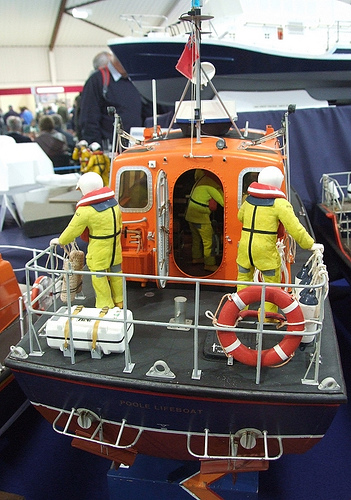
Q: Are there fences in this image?
A: No, there are no fences.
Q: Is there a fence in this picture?
A: No, there are no fences.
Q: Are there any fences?
A: No, there are no fences.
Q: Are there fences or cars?
A: No, there are no fences or cars.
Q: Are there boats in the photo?
A: Yes, there is a boat.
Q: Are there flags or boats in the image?
A: Yes, there is a boat.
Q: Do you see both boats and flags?
A: Yes, there are both a boat and a flag.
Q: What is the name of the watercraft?
A: The watercraft is a boat.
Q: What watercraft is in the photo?
A: The watercraft is a boat.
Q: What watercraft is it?
A: The watercraft is a boat.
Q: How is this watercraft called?
A: That is a boat.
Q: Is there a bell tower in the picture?
A: No, there are no bell towers.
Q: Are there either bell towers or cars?
A: No, there are no bell towers or cars.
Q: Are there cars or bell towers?
A: No, there are no bell towers or cars.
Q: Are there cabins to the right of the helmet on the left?
A: Yes, there is a cabin to the right of the helmet.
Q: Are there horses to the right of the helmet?
A: No, there is a cabin to the right of the helmet.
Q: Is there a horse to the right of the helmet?
A: No, there is a cabin to the right of the helmet.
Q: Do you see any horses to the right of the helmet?
A: No, there is a cabin to the right of the helmet.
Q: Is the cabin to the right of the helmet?
A: Yes, the cabin is to the right of the helmet.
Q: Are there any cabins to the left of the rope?
A: Yes, there is a cabin to the left of the rope.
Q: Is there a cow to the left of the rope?
A: No, there is a cabin to the left of the rope.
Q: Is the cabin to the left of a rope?
A: Yes, the cabin is to the left of a rope.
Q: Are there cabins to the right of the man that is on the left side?
A: Yes, there is a cabin to the right of the man.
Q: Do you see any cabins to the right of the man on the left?
A: Yes, there is a cabin to the right of the man.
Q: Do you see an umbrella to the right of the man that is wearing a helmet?
A: No, there is a cabin to the right of the man.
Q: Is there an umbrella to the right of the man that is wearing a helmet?
A: No, there is a cabin to the right of the man.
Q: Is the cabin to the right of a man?
A: Yes, the cabin is to the right of a man.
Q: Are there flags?
A: Yes, there is a flag.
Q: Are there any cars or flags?
A: Yes, there is a flag.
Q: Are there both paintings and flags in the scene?
A: No, there is a flag but no paintings.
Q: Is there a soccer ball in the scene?
A: No, there are no soccer balls.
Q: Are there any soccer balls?
A: No, there are no soccer balls.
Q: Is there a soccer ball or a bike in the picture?
A: No, there are no soccer balls or bikes.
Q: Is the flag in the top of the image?
A: Yes, the flag is in the top of the image.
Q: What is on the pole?
A: The flag is on the pole.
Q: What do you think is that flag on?
A: The flag is on the pole.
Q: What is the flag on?
A: The flag is on the pole.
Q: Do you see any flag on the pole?
A: Yes, there is a flag on the pole.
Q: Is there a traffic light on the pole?
A: No, there is a flag on the pole.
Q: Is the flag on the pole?
A: Yes, the flag is on the pole.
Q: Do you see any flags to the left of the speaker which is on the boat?
A: Yes, there is a flag to the left of the speaker.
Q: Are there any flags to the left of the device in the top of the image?
A: Yes, there is a flag to the left of the speaker.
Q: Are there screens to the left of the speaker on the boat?
A: No, there is a flag to the left of the speaker.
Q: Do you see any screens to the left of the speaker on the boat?
A: No, there is a flag to the left of the speaker.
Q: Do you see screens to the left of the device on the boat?
A: No, there is a flag to the left of the speaker.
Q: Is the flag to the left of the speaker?
A: Yes, the flag is to the left of the speaker.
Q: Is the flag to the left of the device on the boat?
A: Yes, the flag is to the left of the speaker.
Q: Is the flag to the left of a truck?
A: No, the flag is to the left of the speaker.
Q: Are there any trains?
A: No, there are no trains.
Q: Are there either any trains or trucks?
A: No, there are no trains or trucks.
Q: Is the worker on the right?
A: Yes, the worker is on the right of the image.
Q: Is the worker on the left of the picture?
A: No, the worker is on the right of the image.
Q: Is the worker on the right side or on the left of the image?
A: The worker is on the right of the image.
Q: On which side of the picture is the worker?
A: The worker is on the right of the image.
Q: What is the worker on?
A: The worker is on the boat.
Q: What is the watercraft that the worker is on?
A: The watercraft is a boat.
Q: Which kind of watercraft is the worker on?
A: The worker is on the boat.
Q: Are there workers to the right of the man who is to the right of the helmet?
A: Yes, there is a worker to the right of the man.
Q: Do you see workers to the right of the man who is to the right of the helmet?
A: Yes, there is a worker to the right of the man.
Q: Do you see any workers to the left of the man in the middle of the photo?
A: No, the worker is to the right of the man.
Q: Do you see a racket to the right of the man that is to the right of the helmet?
A: No, there is a worker to the right of the man.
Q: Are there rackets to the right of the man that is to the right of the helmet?
A: No, there is a worker to the right of the man.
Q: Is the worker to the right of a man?
A: Yes, the worker is to the right of a man.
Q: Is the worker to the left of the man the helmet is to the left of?
A: No, the worker is to the right of the man.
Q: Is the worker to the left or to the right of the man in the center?
A: The worker is to the right of the man.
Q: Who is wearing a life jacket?
A: The worker is wearing a life jacket.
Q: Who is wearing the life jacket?
A: The worker is wearing a life jacket.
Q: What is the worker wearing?
A: The worker is wearing a life jacket.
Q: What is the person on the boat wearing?
A: The worker is wearing a life jacket.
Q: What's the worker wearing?
A: The worker is wearing a life jacket.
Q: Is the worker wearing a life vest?
A: Yes, the worker is wearing a life vest.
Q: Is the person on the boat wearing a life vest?
A: Yes, the worker is wearing a life vest.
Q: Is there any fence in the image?
A: No, there are no fences.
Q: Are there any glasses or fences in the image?
A: No, there are no fences or glasses.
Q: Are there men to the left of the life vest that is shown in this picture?
A: Yes, there is a man to the left of the life vest.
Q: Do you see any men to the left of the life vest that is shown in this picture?
A: Yes, there is a man to the left of the life vest.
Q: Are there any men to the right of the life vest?
A: No, the man is to the left of the life vest.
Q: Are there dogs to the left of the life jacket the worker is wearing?
A: No, there is a man to the left of the life jacket.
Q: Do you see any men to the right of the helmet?
A: Yes, there is a man to the right of the helmet.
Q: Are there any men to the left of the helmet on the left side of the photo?
A: No, the man is to the right of the helmet.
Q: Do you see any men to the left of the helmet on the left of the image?
A: No, the man is to the right of the helmet.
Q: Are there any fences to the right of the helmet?
A: No, there is a man to the right of the helmet.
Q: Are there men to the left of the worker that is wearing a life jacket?
A: Yes, there is a man to the left of the worker.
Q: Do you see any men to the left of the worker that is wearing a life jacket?
A: Yes, there is a man to the left of the worker.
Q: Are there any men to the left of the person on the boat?
A: Yes, there is a man to the left of the worker.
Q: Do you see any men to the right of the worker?
A: No, the man is to the left of the worker.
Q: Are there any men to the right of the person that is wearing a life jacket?
A: No, the man is to the left of the worker.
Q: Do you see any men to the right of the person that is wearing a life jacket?
A: No, the man is to the left of the worker.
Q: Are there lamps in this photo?
A: No, there are no lamps.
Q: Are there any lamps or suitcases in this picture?
A: No, there are no lamps or suitcases.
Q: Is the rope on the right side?
A: Yes, the rope is on the right of the image.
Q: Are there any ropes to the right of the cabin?
A: Yes, there is a rope to the right of the cabin.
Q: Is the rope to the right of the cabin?
A: Yes, the rope is to the right of the cabin.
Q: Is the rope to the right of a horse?
A: No, the rope is to the right of the cabin.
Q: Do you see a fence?
A: No, there are no fences.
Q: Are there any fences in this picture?
A: No, there are no fences.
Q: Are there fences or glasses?
A: No, there are no fences or glasses.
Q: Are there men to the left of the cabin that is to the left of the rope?
A: Yes, there is a man to the left of the cabin.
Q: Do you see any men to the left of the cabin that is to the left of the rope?
A: Yes, there is a man to the left of the cabin.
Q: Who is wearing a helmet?
A: The man is wearing a helmet.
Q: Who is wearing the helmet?
A: The man is wearing a helmet.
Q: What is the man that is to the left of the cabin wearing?
A: The man is wearing a helmet.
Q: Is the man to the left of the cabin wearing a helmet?
A: Yes, the man is wearing a helmet.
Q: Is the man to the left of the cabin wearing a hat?
A: No, the man is wearing a helmet.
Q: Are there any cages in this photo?
A: No, there are no cages.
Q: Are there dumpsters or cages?
A: No, there are no cages or dumpsters.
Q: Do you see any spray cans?
A: No, there are no spray cans.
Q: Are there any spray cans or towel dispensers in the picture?
A: No, there are no spray cans or towel dispensers.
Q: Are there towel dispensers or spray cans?
A: No, there are no spray cans or towel dispensers.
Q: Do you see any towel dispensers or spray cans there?
A: No, there are no spray cans or towel dispensers.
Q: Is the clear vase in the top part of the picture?
A: Yes, the vase is in the top of the image.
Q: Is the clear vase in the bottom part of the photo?
A: No, the vase is in the top of the image.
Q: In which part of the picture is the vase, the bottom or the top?
A: The vase is in the top of the image.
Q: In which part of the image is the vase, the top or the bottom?
A: The vase is in the top of the image.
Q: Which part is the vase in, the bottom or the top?
A: The vase is in the top of the image.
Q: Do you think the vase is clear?
A: Yes, the vase is clear.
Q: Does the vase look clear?
A: Yes, the vase is clear.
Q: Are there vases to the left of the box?
A: Yes, there is a vase to the left of the box.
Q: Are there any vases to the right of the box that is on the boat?
A: No, the vase is to the left of the box.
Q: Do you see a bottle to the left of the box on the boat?
A: No, there is a vase to the left of the box.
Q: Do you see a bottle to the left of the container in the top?
A: No, there is a vase to the left of the box.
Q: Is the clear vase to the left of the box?
A: Yes, the vase is to the left of the box.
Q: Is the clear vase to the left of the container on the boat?
A: Yes, the vase is to the left of the box.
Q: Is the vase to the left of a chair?
A: No, the vase is to the left of the box.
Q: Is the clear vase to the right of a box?
A: No, the vase is to the left of a box.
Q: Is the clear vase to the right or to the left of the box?
A: The vase is to the left of the box.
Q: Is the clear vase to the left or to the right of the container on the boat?
A: The vase is to the left of the box.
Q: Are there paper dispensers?
A: No, there are no paper dispensers.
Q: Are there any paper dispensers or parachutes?
A: No, there are no paper dispensers or parachutes.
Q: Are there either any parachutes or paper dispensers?
A: No, there are no paper dispensers or parachutes.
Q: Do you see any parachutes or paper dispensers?
A: No, there are no paper dispensers or parachutes.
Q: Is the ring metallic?
A: Yes, the ring is metallic.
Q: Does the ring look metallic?
A: Yes, the ring is metallic.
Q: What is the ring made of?
A: The ring is made of metal.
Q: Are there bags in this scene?
A: Yes, there is a bag.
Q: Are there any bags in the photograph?
A: Yes, there is a bag.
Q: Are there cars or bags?
A: Yes, there is a bag.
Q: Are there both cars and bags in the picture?
A: No, there is a bag but no cars.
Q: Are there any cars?
A: No, there are no cars.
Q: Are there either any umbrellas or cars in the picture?
A: No, there are no cars or umbrellas.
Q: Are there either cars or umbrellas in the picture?
A: No, there are no cars or umbrellas.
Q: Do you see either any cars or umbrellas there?
A: No, there are no cars or umbrellas.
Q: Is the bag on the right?
A: Yes, the bag is on the right of the image.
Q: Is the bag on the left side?
A: No, the bag is on the right of the image.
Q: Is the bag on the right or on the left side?
A: The bag is on the right of the image.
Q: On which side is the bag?
A: The bag is on the right of the image.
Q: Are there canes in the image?
A: No, there are no canes.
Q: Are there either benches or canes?
A: No, there are no canes or benches.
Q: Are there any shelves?
A: No, there are no shelves.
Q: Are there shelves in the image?
A: No, there are no shelves.